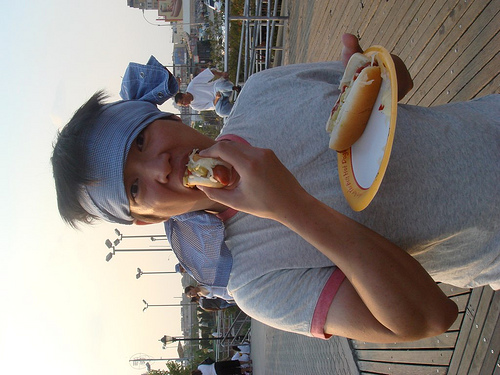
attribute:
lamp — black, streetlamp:
[148, 317, 225, 367]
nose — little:
[147, 148, 176, 183]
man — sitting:
[161, 68, 233, 115]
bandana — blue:
[55, 51, 172, 236]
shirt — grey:
[159, 47, 498, 329]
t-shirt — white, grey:
[218, 56, 489, 342]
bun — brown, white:
[321, 49, 385, 155]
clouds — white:
[2, 10, 182, 105]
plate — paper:
[332, 40, 400, 212]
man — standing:
[49, 31, 498, 342]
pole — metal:
[138, 295, 210, 317]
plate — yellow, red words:
[338, 44, 398, 212]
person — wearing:
[43, 30, 499, 347]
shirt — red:
[142, 83, 480, 335]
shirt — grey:
[204, 54, 499, 342]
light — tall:
[105, 237, 177, 265]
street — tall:
[106, 229, 124, 264]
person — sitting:
[174, 74, 244, 118]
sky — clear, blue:
[0, 22, 70, 130]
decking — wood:
[323, 25, 494, 81]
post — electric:
[160, 320, 256, 346]